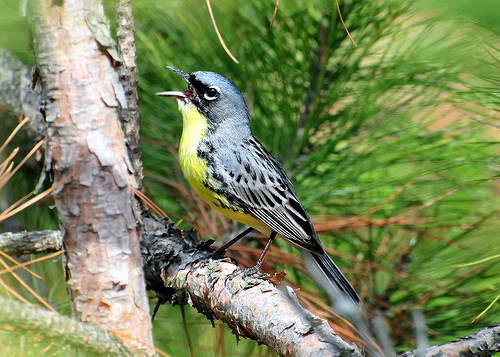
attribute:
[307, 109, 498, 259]
grass — yellow, tall , green 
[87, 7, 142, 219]
bark — white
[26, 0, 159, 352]
trunk — orange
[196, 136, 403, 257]
wing — black , white 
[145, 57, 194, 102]
beak — open 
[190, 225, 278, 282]
legs — thin , black 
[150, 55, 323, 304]
bird — yellow , gray 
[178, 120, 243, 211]
chest — yellow 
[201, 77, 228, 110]
eye — black 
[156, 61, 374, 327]
bird — yellow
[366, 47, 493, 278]
grass — tall , green , yellow